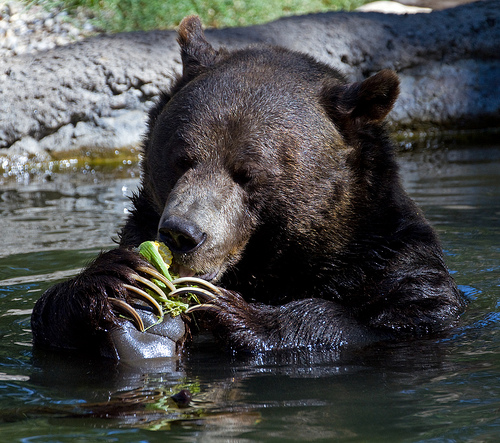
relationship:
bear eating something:
[28, 15, 468, 373] [108, 228, 196, 323]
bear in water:
[28, 15, 468, 373] [43, 107, 496, 433]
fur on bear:
[28, 10, 470, 403] [28, 15, 468, 373]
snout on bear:
[153, 214, 206, 252] [28, 15, 468, 373]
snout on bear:
[148, 214, 212, 266] [28, 15, 468, 373]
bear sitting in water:
[28, 15, 468, 373] [403, 146, 498, 436]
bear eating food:
[28, 15, 468, 373] [119, 235, 192, 324]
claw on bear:
[138, 263, 179, 290] [28, 15, 468, 373]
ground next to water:
[5, 1, 498, 164] [1, 127, 499, 441]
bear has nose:
[28, 15, 468, 373] [150, 210, 217, 263]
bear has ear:
[28, 15, 468, 373] [322, 51, 410, 134]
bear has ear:
[28, 15, 468, 373] [174, 13, 229, 95]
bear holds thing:
[28, 15, 468, 373] [134, 242, 189, 316]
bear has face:
[28, 15, 468, 373] [160, 117, 293, 278]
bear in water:
[28, 15, 468, 373] [16, 179, 488, 430]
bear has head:
[28, 15, 468, 373] [110, 15, 392, 277]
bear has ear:
[28, 15, 468, 373] [339, 65, 406, 119]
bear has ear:
[28, 15, 468, 373] [160, 5, 229, 66]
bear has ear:
[28, 15, 468, 373] [161, 7, 211, 62]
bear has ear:
[28, 15, 468, 373] [339, 60, 399, 119]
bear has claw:
[28, 15, 468, 373] [107, 294, 145, 338]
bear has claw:
[28, 15, 468, 373] [120, 281, 167, 321]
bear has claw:
[28, 15, 468, 373] [127, 270, 171, 304]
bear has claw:
[28, 15, 468, 373] [139, 258, 181, 293]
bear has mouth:
[28, 15, 468, 373] [159, 244, 234, 285]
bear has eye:
[28, 15, 468, 373] [168, 148, 195, 181]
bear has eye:
[28, 15, 468, 373] [224, 155, 254, 193]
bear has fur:
[28, 15, 468, 373] [161, 67, 451, 369]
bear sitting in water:
[68, 15, 447, 439] [348, 369, 485, 438]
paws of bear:
[80, 246, 267, 403] [28, 15, 468, 373]